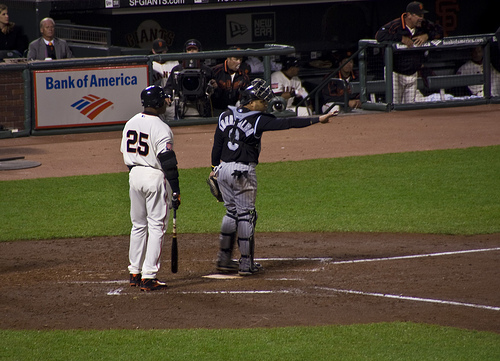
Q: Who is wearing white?
A: Baseball player.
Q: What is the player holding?
A: Black bat.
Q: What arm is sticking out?
A: Right.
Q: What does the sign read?
A: Bank of America.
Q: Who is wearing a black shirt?
A: Catcher.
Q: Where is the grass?
A: On the baseball field.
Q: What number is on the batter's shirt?
A: 25.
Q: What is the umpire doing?
A: Talking to the players.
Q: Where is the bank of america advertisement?
A: In the background behind the players.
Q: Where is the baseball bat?
A: In the batter's hand.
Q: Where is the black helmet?
A: On player 25's head.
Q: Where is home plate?
A: Under the umpire.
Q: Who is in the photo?
A: A batter.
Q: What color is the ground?
A: Green and brown.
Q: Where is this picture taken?
A: Ball field.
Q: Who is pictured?
A: Catcher and hitter.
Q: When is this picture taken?
A: During game.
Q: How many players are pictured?
A: 2.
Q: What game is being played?
A: Baseball.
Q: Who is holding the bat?
A: Baseball player.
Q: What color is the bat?
A: Black.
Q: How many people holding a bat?
A: One.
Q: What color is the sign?
A: White, red and blue.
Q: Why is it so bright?
A: Sun light.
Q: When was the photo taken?
A: Day time.